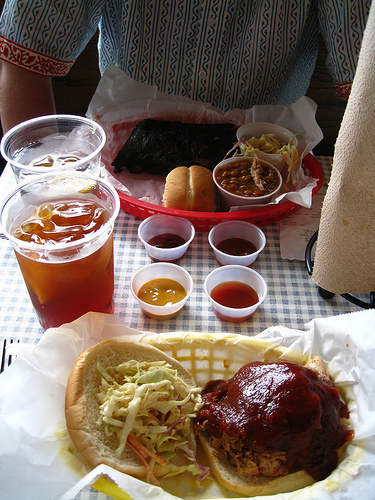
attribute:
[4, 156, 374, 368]
table — small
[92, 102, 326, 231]
basket — plastic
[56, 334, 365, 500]
basket — yellow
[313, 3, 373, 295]
paper towel — brown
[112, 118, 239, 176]
meat — bbq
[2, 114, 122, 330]
drinks — cold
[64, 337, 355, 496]
sandwich — covered, bbq, ready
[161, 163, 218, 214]
roll — bread, ready